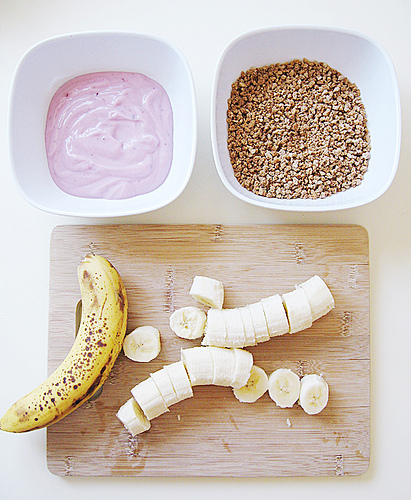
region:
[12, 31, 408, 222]
Two bowls filled with nuts and yogurt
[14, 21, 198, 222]
White bowl with pink yogurt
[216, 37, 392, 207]
White bowl with brown nuts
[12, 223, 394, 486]
Cutting board with sliced and whole bananas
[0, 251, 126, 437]
Whole yellow ripened banana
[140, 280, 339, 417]
Sliced unpeeled bananas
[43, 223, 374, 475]
Brown wooden cutting board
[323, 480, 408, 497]
Edge of white counter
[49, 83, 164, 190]
Creamy pink yogurt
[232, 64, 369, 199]
Brown unevenly chopped nuts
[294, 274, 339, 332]
yellow slice of banana on wooden board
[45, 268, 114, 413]
banana with yellow peel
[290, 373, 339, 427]
yellow slice of banana on wooden board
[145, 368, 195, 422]
yellow slice of banana on wooden board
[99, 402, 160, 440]
yellow slice of banana on wooden board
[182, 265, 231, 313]
yellow slice of banana on wooden board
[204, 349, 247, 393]
yellow slice of banana on wooden board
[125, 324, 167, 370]
yellow slice of banana on wooden board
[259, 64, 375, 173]
nuts in white bowl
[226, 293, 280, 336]
yellow slice of banana on wooden board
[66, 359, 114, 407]
Brown line on the banana.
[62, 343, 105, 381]
Brown spots on the banana.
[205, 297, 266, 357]
Slices of the banana.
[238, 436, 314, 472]
The cutting board is wooden.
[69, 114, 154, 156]
Yogurt in the bowl.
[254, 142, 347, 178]
Granola in a bowl.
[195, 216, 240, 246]
Dark spot on the cutting board.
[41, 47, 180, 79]
The bowl is white.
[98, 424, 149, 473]
Banana juices on the cutting board.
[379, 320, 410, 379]
The counter is white.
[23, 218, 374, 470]
Sliced bananas on a wooden cutting board.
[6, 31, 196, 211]
Pink yogurt in a white bowl.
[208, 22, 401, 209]
Granola in a white bowl.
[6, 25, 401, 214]
Two white bowls sitting side by side.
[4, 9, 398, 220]
Two white bowls on top of a white surface.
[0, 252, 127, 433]
A yellow banana on a cutting board.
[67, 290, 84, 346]
A portion of the cutting board's handle.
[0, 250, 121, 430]
Black bruising on the banana peel.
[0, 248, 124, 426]
Brown spots on a banana peel.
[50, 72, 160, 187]
Pink specks of fruit in the yogurt.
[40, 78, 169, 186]
Yogurt in a bowl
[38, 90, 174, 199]
Yogurt in a dish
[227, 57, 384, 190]
Granola in a bowl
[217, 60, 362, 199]
Granola in a dish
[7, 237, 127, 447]
Banana on a cutting board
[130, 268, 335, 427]
Sliced pieces of banana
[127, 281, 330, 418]
Banana slices on a cutting board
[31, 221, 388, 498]
A cutting board with bananas on it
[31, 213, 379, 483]
A wooden cutting board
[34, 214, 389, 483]
A bamboo cutting board